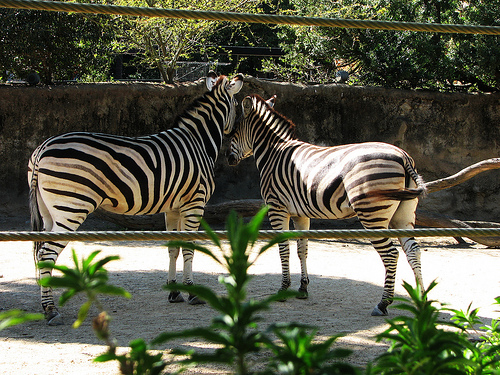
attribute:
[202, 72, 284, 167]
heads — zebra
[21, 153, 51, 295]
tail — zebra, long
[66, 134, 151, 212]
stripe — zebra's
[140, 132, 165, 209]
stripe — zebra's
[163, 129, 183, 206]
stripe — zebra's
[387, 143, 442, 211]
tail — swishing, zebra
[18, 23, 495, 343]
zebras — snuggling